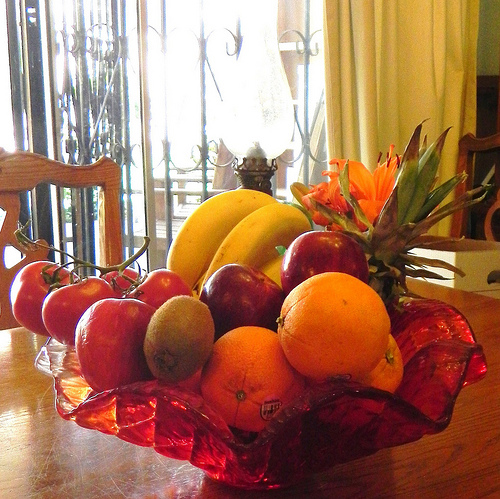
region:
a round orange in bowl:
[270, 275, 403, 375]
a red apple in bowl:
[203, 253, 281, 318]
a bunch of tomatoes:
[0, 247, 141, 323]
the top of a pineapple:
[366, 121, 473, 273]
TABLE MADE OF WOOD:
[418, 437, 469, 480]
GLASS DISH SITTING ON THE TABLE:
[291, 403, 369, 468]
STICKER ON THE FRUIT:
[257, 398, 284, 420]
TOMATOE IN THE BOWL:
[55, 304, 76, 323]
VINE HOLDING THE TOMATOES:
[21, 225, 146, 284]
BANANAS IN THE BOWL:
[206, 191, 256, 257]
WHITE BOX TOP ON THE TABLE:
[477, 253, 492, 277]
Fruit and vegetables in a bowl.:
[8, 126, 495, 495]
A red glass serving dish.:
[28, 282, 492, 487]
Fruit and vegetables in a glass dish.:
[11, 124, 491, 490]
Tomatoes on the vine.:
[11, 220, 192, 341]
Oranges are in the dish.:
[200, 266, 432, 417]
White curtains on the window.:
[322, 0, 484, 250]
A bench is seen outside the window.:
[128, 139, 310, 228]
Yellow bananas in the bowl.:
[134, 182, 315, 294]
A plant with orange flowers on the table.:
[286, 126, 492, 296]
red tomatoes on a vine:
[13, 246, 175, 330]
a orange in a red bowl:
[279, 258, 393, 399]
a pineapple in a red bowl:
[373, 126, 468, 316]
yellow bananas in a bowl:
[160, 175, 311, 295]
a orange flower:
[310, 134, 405, 242]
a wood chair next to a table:
[0, 152, 132, 337]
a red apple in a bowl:
[275, 227, 376, 287]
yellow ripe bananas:
[163, 179, 317, 293]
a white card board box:
[403, 226, 498, 296]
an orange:
[293, 288, 389, 373]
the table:
[31, 452, 103, 487]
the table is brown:
[18, 443, 93, 494]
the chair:
[11, 159, 71, 190]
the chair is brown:
[105, 171, 124, 248]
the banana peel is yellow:
[231, 220, 276, 254]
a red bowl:
[413, 308, 463, 380]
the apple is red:
[209, 263, 269, 315]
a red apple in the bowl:
[209, 261, 270, 312]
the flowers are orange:
[363, 159, 392, 212]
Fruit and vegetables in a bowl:
[8, 120, 498, 490]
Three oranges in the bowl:
[201, 269, 404, 433]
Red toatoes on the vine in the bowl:
[11, 242, 199, 342]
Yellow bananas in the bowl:
[166, 188, 308, 288]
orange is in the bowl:
[278, 265, 390, 374]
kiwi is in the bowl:
[144, 290, 215, 379]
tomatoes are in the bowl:
[9, 227, 191, 349]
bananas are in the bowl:
[167, 187, 314, 294]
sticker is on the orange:
[261, 397, 281, 419]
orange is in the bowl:
[199, 322, 307, 432]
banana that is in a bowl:
[184, 182, 281, 286]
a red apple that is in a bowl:
[205, 259, 267, 321]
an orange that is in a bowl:
[257, 278, 399, 383]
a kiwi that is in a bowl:
[130, 283, 217, 383]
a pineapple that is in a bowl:
[337, 169, 437, 333]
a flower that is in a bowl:
[328, 162, 396, 226]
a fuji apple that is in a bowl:
[74, 289, 156, 397]